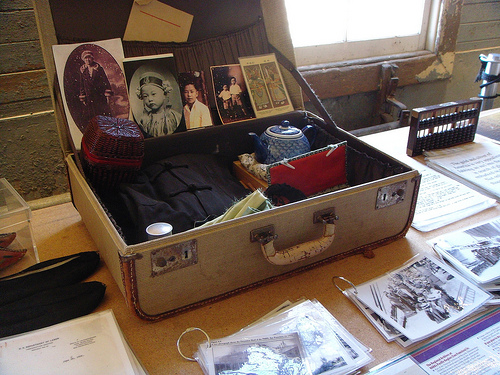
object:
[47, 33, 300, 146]
photographs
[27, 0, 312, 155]
lid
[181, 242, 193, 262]
keyhole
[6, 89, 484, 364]
items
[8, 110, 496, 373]
desktop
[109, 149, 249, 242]
cloth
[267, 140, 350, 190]
lid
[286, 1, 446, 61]
window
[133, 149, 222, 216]
shirt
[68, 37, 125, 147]
picture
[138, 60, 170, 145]
picture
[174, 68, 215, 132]
picture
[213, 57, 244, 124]
picture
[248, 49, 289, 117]
picture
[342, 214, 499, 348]
picture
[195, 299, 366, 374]
picture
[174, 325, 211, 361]
ring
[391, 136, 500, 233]
paper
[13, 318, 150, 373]
letterhead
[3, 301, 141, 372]
papers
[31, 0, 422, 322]
suitcase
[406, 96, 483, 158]
abacus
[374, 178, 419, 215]
lock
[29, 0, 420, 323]
briefcase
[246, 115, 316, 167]
side burn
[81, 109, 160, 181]
wicker box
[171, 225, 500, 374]
photographs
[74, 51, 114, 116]
lady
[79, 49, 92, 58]
hat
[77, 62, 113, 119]
coat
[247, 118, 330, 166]
teapot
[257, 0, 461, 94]
window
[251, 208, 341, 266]
handle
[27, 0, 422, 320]
old suitcase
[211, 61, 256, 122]
photo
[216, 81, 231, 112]
child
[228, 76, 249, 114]
child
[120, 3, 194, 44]
envelope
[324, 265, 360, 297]
ring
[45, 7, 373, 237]
mementos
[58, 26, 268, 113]
pocket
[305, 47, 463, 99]
sill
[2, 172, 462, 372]
table